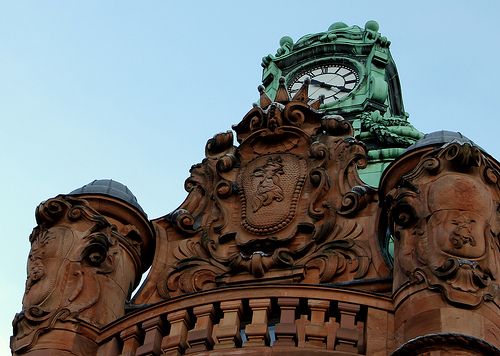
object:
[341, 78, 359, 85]
numerals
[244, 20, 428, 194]
structure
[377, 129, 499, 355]
structure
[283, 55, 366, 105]
clock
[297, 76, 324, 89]
hands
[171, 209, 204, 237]
curl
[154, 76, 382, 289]
columns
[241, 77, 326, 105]
top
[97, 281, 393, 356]
structure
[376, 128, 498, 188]
top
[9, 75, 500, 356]
stonework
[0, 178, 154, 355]
section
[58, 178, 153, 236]
domes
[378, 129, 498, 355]
section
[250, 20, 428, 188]
building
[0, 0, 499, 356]
sky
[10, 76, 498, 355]
sculptures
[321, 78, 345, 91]
hands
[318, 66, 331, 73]
numbers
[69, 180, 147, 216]
roof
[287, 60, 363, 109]
face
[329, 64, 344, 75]
number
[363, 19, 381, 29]
ball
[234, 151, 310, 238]
insignia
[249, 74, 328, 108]
crown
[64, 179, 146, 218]
top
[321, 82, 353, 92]
minute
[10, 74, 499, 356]
building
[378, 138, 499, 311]
fancy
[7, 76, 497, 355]
tower